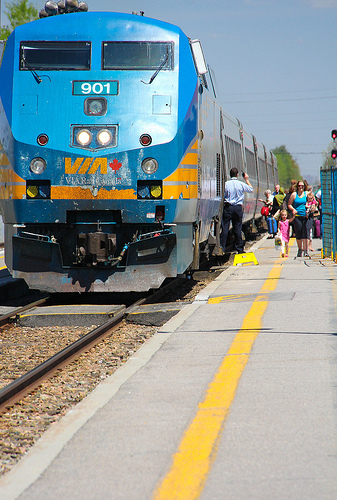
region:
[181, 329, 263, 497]
yellow painted straight line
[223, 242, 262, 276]
yellow small stepping stool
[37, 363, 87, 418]
gravel underneath tracks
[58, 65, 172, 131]
number 901 on train front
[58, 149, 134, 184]
VIA yellow text on train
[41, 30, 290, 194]
blue and yellow train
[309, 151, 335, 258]
blue metallic tall fence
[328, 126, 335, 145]
small red traffic lights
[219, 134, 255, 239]
conductor standing in train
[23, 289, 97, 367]
rusted brown train tracks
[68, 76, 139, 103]
Number 901 on front of train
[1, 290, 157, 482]
Gravel bed for train tracks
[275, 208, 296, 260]
Small girl wearing pink and yellow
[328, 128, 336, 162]
Red lights by train station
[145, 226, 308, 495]
Yellow line down foot path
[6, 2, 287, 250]
Blue passenger train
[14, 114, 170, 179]
Red and white lights on front of train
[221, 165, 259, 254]
Man in light blue and dark blue uniform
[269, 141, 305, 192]
Green trees behind train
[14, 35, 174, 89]
Windshield wipers on train windows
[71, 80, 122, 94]
numbers "901" on the train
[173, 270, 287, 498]
yellow stripe on the walkway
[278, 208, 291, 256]
young girl wearing pink shirt and white pants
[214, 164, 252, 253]
train conductor holding a walkie-talkie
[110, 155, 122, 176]
red maple leaf on train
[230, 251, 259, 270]
yellow stepstool for conductor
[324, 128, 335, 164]
two red stoplights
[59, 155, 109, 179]
yellow letters "via" on train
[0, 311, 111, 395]
train tracks and gravel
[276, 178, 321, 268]
woman wearing blue tank top who is escorting two children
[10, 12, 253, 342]
blue and yellow train on tracks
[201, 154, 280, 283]
conductor outside of train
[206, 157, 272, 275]
main in blue shirt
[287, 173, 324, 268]
woman in blue shirt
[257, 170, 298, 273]
child in pink shirt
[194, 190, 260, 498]
yellow line on side walk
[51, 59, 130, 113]
number 901 on nose of train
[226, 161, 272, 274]
man on yellow step stool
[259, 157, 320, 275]
people waiting for train on side walk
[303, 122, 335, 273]
green fence with red traffic lights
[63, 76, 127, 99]
the numbers 901 on the front of the train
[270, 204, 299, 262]
a small child wearing pink clothes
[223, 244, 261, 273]
a yellow footstool a man is standing on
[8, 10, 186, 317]
the front of a blue train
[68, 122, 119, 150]
headlights of the blue train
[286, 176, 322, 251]
a woman wearing a blue shirt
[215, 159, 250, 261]
a man holding a walkie talkie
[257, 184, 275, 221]
a woman holding a red bag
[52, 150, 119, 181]
the letters via on the front of the train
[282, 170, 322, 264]
a woman holding a baby